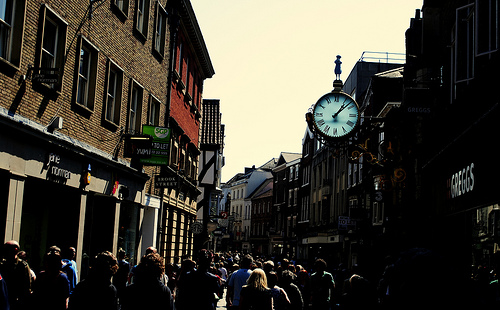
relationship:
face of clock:
[315, 95, 357, 132] [310, 89, 360, 139]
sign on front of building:
[443, 162, 478, 201] [419, 16, 496, 232]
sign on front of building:
[120, 137, 173, 167] [1, 0, 216, 294]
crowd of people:
[1, 238, 364, 308] [2, 238, 367, 306]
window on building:
[297, 73, 367, 150] [1, 0, 216, 294]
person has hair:
[234, 267, 273, 307] [246, 267, 270, 289]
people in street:
[143, 194, 390, 306] [51, 258, 489, 309]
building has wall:
[165, 2, 215, 273] [163, 25, 203, 184]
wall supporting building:
[163, 25, 203, 184] [150, 2, 217, 272]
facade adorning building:
[249, 198, 275, 258] [248, 183, 277, 248]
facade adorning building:
[310, 130, 371, 272] [301, 47, 409, 279]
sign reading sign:
[447, 162, 477, 200] [447, 162, 477, 200]